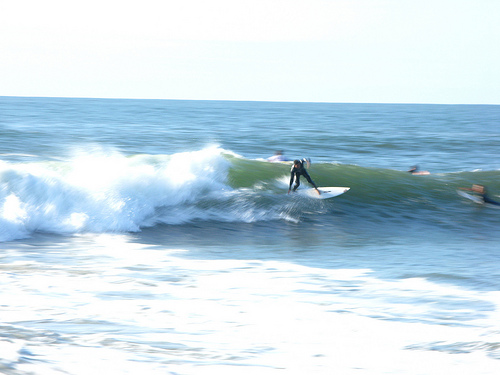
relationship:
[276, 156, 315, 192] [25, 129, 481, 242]
surfer on wave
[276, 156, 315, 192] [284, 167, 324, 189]
surfer in wetsuit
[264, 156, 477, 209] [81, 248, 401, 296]
people in water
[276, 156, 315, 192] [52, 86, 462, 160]
surfer in ocean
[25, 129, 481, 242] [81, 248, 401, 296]
wave on water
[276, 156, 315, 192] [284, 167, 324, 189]
surfer wearing wetsuit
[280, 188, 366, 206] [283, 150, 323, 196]
surfboard has person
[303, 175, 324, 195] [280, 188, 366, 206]
leg on surfboard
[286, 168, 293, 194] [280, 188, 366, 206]
arm holding surfboard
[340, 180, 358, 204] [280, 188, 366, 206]
tip of surfboard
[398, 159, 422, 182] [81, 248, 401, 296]
object in water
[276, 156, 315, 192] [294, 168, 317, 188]
surfer in suit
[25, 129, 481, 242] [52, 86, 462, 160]
wave in ocean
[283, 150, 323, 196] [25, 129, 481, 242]
person on wave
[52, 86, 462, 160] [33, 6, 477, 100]
ocean meets sky